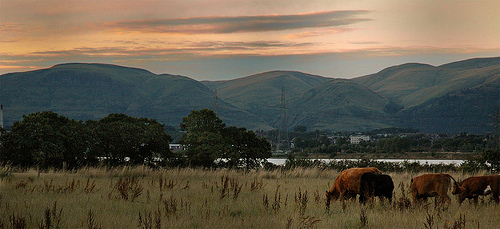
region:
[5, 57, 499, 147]
mountains are in the background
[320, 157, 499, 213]
animals in the field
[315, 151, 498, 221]
cows in a pasture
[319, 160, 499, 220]
cows in a field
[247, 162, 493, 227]
some of the cows are grazing in the grass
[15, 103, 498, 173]
trees are beside the field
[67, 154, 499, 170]
a body of water is behind the trees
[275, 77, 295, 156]
a metal tower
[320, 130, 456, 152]
buildings at the base of the mountains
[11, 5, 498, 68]
the sun is setting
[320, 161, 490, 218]
cows in tall grass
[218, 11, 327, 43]
gray clouds in daytime sky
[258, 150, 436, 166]
body of water behind bushes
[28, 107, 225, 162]
trees with green leaves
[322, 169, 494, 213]
brown cows grazing on grass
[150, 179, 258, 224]
tall brown dried grass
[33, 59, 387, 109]
mountain range on horizon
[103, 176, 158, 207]
dark brown weeds in grass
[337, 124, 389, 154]
building in front of mountain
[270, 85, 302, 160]
tall tower behind water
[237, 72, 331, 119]
green hill are visible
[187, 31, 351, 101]
green hill are visible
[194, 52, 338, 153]
green hill are visible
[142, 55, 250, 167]
green hill are visible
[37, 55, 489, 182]
a beautiful mountain range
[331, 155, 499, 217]
cows are grazing in the pasture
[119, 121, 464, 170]
a lake is in the background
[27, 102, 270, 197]
the trees are very full & lush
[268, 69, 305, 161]
a modern day tower ruins the photo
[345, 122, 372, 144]
seems to be a house back there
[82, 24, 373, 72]
the sky is gorgeous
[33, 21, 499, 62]
this sky could be a sunset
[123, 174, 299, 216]
the weeds are very high in this pasture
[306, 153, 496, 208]
the cows seem fat; they must eat well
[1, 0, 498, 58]
a red sky sunrise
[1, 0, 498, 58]
an orange sky sunset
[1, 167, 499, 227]
cows grazing in the tall grass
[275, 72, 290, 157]
a cellular communications tower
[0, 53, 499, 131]
rolling hills in the distance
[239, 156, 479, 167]
a river bordering the field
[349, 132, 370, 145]
a tall commercial building across the river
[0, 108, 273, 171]
tall trees at the river bank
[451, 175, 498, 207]
a brown and white cow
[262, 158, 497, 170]
shrubs and bushes at the river bank